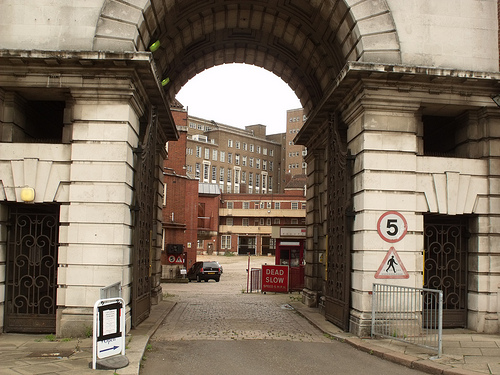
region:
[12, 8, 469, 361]
Picture taken outdoors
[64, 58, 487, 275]
Picture taken during the day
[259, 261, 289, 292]
A sign says Dead Slow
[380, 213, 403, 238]
A sign has the number 5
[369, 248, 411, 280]
The sign is a triangle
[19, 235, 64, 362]
The door is made of metal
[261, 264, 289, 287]
The sign is red and white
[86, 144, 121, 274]
The building is made of large pieces of concrete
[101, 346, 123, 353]
An arrow points on the sign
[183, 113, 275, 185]
The building has lots of windows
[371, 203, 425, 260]
the number is 5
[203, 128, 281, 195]
the building is brown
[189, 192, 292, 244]
the building is red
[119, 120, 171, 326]
the gate is brown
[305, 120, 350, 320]
the gate is brown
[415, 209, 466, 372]
the gate is brown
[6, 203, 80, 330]
the gate is brown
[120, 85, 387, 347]
the gate is open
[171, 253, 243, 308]
the car is parked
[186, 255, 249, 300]
the car is black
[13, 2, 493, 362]
Large cement archway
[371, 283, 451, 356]
An aluminum fence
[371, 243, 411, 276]
Sign with picture of a man walking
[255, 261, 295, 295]
A red sign that says dead slow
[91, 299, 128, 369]
A white and black direction sign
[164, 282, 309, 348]
A cobbleston street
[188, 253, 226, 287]
A black suv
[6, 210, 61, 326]
A brown decorative scroll gate on left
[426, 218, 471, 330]
A brown decorative scroll gate on right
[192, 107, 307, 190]
A large light tan brick building with white trim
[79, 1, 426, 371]
building with an arch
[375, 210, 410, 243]
red and white circle sign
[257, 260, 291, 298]
red and white square sign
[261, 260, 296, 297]
sign stating DEAD SLOW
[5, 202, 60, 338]
door made of iron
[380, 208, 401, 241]
a black number five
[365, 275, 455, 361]
small metal barrier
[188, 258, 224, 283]
a black vehicle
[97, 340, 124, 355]
black arrow pointing right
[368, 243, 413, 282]
triangle sign with a black pedestrian on it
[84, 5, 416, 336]
a stone archway with gates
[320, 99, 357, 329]
A gate in an archway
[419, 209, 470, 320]
A gate in a door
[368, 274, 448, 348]
A metal fence on the sidewalk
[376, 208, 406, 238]
A circular sign with the number 5 on it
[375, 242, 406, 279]
A caution sign for people walking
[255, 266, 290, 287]
A sign that says Dead Slow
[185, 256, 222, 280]
A car in the distance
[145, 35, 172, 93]
Lights near the top of the arch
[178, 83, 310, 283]
Buildings in the distance